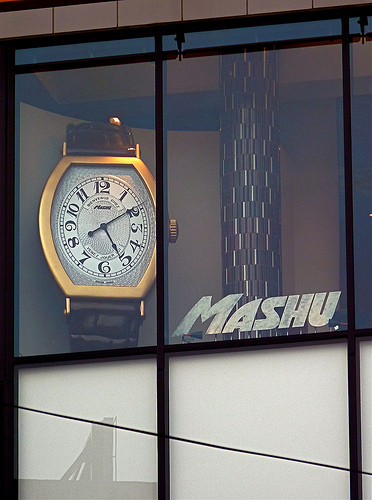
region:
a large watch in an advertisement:
[39, 115, 181, 349]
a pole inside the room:
[205, 56, 294, 330]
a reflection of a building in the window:
[16, 414, 152, 499]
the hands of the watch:
[84, 197, 142, 268]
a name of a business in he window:
[172, 287, 336, 333]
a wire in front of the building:
[12, 400, 370, 469]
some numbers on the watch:
[61, 176, 102, 276]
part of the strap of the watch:
[60, 297, 144, 353]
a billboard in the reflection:
[57, 417, 115, 480]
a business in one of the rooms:
[4, 41, 365, 339]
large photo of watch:
[57, 125, 142, 309]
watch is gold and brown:
[64, 118, 130, 326]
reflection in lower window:
[64, 404, 125, 482]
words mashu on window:
[188, 283, 310, 333]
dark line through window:
[191, 422, 255, 476]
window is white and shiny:
[213, 402, 287, 479]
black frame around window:
[10, 31, 47, 52]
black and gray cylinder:
[227, 80, 266, 254]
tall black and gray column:
[233, 101, 267, 182]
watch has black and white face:
[62, 174, 128, 290]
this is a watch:
[44, 134, 141, 331]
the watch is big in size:
[36, 117, 152, 346]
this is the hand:
[72, 303, 131, 344]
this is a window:
[162, 113, 349, 324]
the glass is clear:
[166, 94, 341, 294]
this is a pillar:
[221, 48, 277, 288]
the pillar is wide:
[221, 68, 279, 290]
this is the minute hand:
[108, 208, 126, 228]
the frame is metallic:
[37, 204, 46, 223]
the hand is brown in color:
[71, 127, 124, 155]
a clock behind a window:
[0, 30, 324, 475]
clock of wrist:
[31, 107, 180, 347]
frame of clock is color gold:
[35, 152, 169, 312]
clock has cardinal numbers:
[32, 148, 175, 301]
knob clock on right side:
[39, 197, 193, 257]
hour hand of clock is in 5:
[87, 215, 136, 277]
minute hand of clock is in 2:
[77, 193, 152, 246]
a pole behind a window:
[212, 40, 290, 348]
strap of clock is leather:
[34, 105, 185, 342]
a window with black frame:
[5, 7, 365, 499]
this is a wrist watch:
[49, 107, 173, 308]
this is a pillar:
[199, 61, 299, 291]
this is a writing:
[172, 290, 334, 355]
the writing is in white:
[175, 293, 300, 341]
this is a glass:
[177, 364, 357, 497]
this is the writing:
[77, 244, 107, 266]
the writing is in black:
[68, 251, 90, 261]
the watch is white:
[87, 206, 108, 216]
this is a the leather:
[73, 122, 118, 148]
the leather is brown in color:
[88, 310, 117, 327]